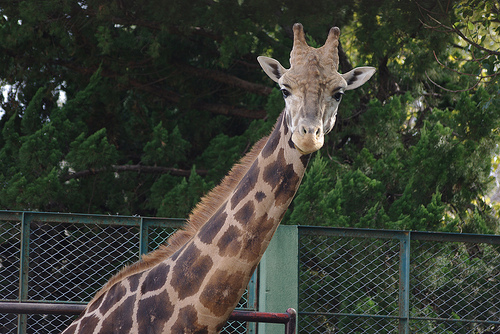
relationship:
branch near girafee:
[0, 0, 500, 234] [84, 37, 349, 332]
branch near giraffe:
[0, 0, 500, 234] [91, 32, 353, 332]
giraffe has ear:
[51, 22, 381, 329] [343, 62, 379, 92]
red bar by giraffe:
[227, 302, 302, 332] [142, 42, 397, 283]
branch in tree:
[54, 143, 209, 189] [24, 8, 499, 214]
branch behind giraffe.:
[0, 0, 500, 234] [75, 18, 396, 315]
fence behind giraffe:
[1, 207, 499, 332] [51, 22, 381, 329]